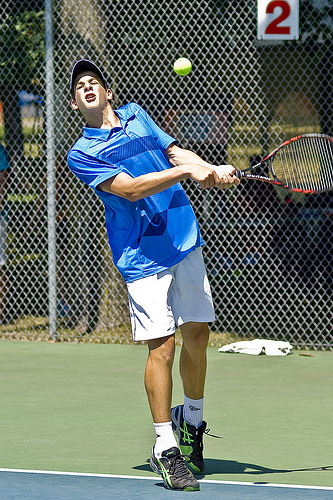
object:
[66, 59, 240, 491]
man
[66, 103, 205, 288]
shirt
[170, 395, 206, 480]
shoes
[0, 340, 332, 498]
tennis court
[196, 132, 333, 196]
tennis racket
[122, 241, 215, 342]
shorts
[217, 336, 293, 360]
cloth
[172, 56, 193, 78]
tennis ball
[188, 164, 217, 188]
hands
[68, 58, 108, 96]
cap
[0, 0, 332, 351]
fence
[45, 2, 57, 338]
post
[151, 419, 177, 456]
sock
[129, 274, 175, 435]
leg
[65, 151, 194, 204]
arm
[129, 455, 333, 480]
shadow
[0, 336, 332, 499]
ground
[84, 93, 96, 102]
mouth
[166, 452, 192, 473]
lace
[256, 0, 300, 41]
number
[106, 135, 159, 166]
stripe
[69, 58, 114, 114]
head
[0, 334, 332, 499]
turf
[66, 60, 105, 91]
visor